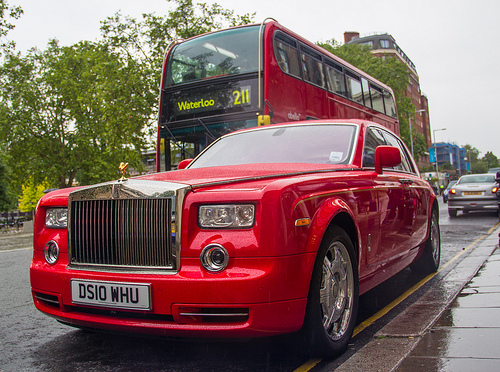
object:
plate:
[67, 277, 154, 311]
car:
[28, 116, 443, 362]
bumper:
[29, 248, 317, 340]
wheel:
[303, 220, 362, 362]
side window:
[359, 124, 397, 173]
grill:
[66, 195, 177, 271]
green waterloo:
[176, 97, 216, 110]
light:
[42, 203, 69, 232]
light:
[194, 202, 260, 230]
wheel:
[408, 196, 442, 275]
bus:
[153, 16, 404, 174]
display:
[157, 74, 263, 125]